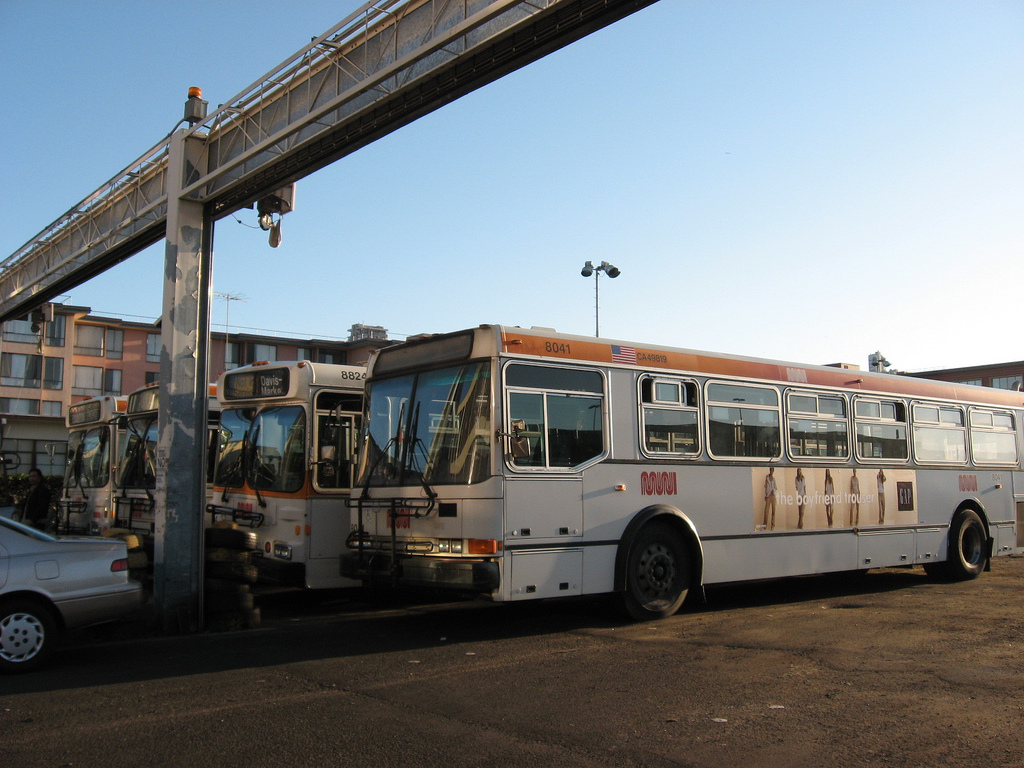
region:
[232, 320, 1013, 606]
buses parked in a row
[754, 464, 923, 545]
clothing ad on the side of the bus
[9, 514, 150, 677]
car parked in front of the bus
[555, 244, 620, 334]
light pole behind the buses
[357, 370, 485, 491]
reflection in the windshield of the bus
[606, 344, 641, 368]
picture of an American flag on the bus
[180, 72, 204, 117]
orange light on top of the pole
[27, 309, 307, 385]
building behind the buses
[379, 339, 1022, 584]
gray and orange bus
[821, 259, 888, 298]
white clouds in the blue sky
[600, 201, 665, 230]
white clouds in the blue sky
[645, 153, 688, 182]
white clouds in the blue sky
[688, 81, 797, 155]
white clouds in the blue sky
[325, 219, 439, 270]
white clouds in the blue sky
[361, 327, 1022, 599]
bus is white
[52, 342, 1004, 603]
the buses are parked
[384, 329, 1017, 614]
front tire on the bus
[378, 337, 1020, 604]
back tire on the bus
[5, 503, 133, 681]
car is parked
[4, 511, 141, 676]
rear tire of a car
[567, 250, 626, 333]
light pole for the parking lot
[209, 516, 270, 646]
tire on a pole for protection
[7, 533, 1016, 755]
lot ground is blacktop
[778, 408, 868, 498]
a bus ont he road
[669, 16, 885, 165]
a sky that is blue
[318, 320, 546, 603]
the front of a bus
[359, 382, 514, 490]
the windshield of a bus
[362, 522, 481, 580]
the bumper of a bus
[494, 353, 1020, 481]
the windows of a bus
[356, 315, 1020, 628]
old white and yellow passenger bus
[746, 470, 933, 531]
sign on passenger bus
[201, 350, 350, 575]
old white and yellow passenger bus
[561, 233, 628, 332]
gray light post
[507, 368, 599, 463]
window in old passenger bus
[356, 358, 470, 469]
window in old passenger bus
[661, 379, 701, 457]
window in old passenger bus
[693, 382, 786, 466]
window in old passenger bus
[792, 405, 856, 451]
window in old passenger bus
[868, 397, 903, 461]
window in old passenger bus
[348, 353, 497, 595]
the front of a bus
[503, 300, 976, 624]
the side of a bus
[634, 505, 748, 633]
the front wheel of a bus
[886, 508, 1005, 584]
the back wheel of a bus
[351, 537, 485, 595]
the bumper of a bus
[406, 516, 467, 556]
the headlight of a bus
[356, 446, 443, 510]
the wiper of a bus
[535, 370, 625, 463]
the window of a bus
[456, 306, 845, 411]
the roof of a bus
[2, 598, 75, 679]
the tire of a car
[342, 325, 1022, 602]
long white bus with orange top strip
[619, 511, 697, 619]
black tire on a bus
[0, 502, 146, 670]
trunk of a silver parked car